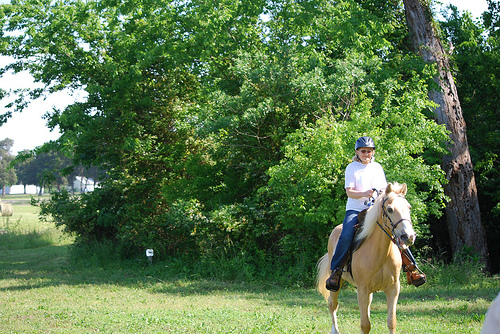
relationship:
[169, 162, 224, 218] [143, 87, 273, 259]
leaves on tree